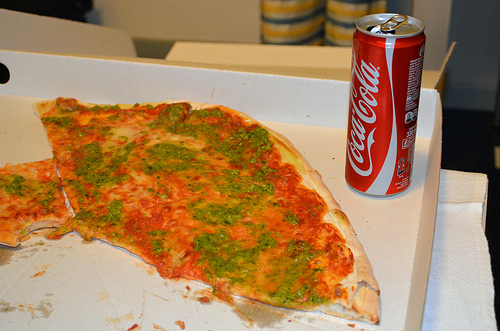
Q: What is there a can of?
A: Soda.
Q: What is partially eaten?
A: Pizza.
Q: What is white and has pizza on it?
A: Box.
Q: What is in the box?
A: Half eaten pizza.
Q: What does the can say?
A: Coca cola.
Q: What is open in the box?
A: Can of coke.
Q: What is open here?
A: Pizza box.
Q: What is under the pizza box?
A: Table.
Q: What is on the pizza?
A: Cheese.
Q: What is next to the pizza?
A: Can of Coke.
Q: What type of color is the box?
A: White.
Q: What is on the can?
A: Coke.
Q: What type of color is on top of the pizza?
A: Green.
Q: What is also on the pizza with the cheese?
A: Pesto.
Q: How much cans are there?
A: 1.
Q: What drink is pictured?
A: Coca cola.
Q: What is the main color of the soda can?
A: Red and white.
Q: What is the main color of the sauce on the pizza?
A: Green.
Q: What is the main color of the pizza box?
A: White.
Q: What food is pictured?
A: Pizza.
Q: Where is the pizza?
A: In a box.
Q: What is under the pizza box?
A: Towel.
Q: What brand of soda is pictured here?
A: Coca-Cola.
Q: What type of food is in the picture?
A: Pizza.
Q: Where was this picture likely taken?
A: A Kitchen.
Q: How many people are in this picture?
A: Zero.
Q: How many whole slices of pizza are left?
A: Three.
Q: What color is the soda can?
A: Red.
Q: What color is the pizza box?
A: White.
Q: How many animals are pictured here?
A: Zero.